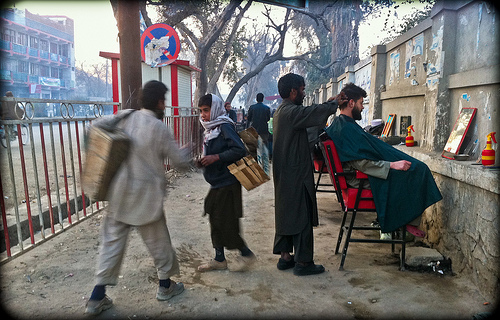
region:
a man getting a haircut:
[279, 67, 441, 274]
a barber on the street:
[272, 71, 339, 275]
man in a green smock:
[332, 84, 440, 239]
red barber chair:
[324, 145, 410, 268]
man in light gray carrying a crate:
[79, 80, 201, 312]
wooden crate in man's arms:
[82, 127, 131, 199]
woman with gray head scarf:
[194, 95, 255, 270]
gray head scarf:
[197, 93, 233, 141]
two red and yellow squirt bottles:
[406, 124, 496, 165]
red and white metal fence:
[2, 95, 244, 262]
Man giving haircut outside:
[271, 69, 381, 199]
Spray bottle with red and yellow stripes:
[480, 129, 497, 165]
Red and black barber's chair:
[319, 138, 374, 254]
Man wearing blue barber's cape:
[326, 81, 423, 218]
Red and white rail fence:
[22, 99, 75, 246]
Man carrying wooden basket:
[80, 79, 169, 199]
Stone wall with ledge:
[457, 153, 489, 278]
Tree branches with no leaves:
[257, 4, 336, 68]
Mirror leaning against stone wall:
[437, 100, 478, 163]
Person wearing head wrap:
[192, 90, 230, 145]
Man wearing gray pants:
[76, 80, 198, 308]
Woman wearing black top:
[181, 92, 263, 272]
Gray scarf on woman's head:
[185, 87, 236, 147]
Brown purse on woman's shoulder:
[216, 119, 270, 196]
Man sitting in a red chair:
[319, 81, 444, 273]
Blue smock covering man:
[329, 112, 446, 229]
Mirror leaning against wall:
[444, 99, 479, 163]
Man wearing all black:
[264, 76, 344, 281]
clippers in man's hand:
[322, 78, 352, 119]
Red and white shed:
[88, 32, 205, 168]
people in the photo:
[105, 57, 395, 216]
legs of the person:
[81, 218, 188, 285]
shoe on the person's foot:
[76, 276, 126, 318]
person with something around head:
[181, 82, 258, 181]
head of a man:
[333, 70, 381, 127]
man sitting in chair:
[335, 65, 422, 182]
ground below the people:
[192, 267, 280, 319]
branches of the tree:
[219, 31, 300, 76]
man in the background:
[247, 88, 275, 120]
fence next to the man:
[4, 92, 81, 198]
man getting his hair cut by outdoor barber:
[267, 63, 412, 269]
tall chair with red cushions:
[324, 130, 408, 265]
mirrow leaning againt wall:
[432, 97, 483, 164]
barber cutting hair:
[265, 56, 355, 276]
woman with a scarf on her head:
[197, 80, 246, 270]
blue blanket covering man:
[318, 115, 442, 242]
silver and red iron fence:
[10, 76, 72, 275]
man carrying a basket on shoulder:
[72, 76, 182, 308]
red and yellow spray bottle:
[474, 126, 498, 173]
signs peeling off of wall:
[386, 15, 448, 92]